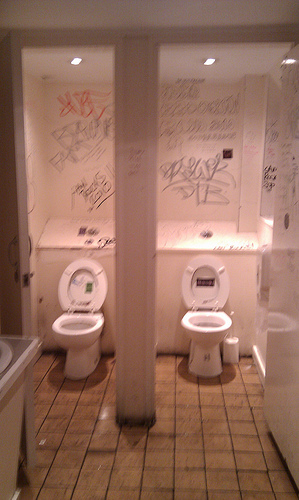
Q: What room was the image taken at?
A: It was taken at the bathroom.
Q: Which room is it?
A: It is a bathroom.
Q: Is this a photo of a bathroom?
A: Yes, it is showing a bathroom.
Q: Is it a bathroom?
A: Yes, it is a bathroom.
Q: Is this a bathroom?
A: Yes, it is a bathroom.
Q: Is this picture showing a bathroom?
A: Yes, it is showing a bathroom.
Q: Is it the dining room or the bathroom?
A: It is the bathroom.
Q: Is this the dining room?
A: No, it is the bathroom.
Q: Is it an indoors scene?
A: Yes, it is indoors.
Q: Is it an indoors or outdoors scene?
A: It is indoors.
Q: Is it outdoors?
A: No, it is indoors.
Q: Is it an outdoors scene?
A: No, it is indoors.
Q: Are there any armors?
A: No, there are no armors.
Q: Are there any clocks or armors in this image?
A: No, there are no armors or clocks.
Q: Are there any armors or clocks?
A: No, there are no armors or clocks.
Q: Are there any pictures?
A: No, there are no pictures.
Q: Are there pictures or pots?
A: No, there are no pictures or pots.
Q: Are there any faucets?
A: No, there are no faucets.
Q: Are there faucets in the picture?
A: No, there are no faucets.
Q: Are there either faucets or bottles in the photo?
A: No, there are no faucets or bottles.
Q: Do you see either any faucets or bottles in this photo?
A: No, there are no faucets or bottles.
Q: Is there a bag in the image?
A: No, there are no bags.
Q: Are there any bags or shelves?
A: No, there are no bags or shelves.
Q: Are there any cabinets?
A: No, there are no cabinets.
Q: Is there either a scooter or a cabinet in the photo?
A: No, there are no cabinets or scooters.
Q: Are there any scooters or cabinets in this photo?
A: No, there are no cabinets or scooters.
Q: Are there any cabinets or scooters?
A: No, there are no cabinets or scooters.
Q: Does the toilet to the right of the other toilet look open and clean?
A: Yes, the toilet is open and clean.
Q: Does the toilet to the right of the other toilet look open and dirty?
A: No, the toilet is open but clean.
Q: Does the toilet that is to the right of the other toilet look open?
A: Yes, the toilet is open.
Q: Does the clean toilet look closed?
A: No, the toilet is open.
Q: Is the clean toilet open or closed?
A: The toilet is open.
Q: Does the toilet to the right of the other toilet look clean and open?
A: Yes, the toilet is clean and open.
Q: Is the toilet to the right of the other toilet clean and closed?
A: No, the toilet is clean but open.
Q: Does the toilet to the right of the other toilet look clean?
A: Yes, the toilet is clean.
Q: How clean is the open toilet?
A: The toilet is clean.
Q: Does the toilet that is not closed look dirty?
A: No, the toilet is clean.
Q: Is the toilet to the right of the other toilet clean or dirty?
A: The toilet is clean.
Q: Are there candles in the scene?
A: No, there are no candles.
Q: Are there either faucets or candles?
A: No, there are no candles or faucets.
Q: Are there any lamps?
A: No, there are no lamps.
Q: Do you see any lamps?
A: No, there are no lamps.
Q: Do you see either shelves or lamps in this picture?
A: No, there are no lamps or shelves.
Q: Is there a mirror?
A: Yes, there is a mirror.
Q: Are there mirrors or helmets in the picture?
A: Yes, there is a mirror.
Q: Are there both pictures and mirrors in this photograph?
A: No, there is a mirror but no pictures.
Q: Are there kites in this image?
A: No, there are no kites.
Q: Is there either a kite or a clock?
A: No, there are no kites or clocks.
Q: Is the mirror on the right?
A: Yes, the mirror is on the right of the image.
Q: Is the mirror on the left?
A: No, the mirror is on the right of the image.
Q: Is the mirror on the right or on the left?
A: The mirror is on the right of the image.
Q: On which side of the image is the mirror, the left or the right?
A: The mirror is on the right of the image.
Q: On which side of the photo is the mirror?
A: The mirror is on the right of the image.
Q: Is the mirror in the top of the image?
A: Yes, the mirror is in the top of the image.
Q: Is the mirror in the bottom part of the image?
A: No, the mirror is in the top of the image.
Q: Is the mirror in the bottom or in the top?
A: The mirror is in the top of the image.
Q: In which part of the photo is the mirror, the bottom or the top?
A: The mirror is in the top of the image.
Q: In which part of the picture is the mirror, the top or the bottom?
A: The mirror is in the top of the image.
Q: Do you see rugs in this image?
A: No, there are no rugs.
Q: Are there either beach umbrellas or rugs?
A: No, there are no rugs or beach umbrellas.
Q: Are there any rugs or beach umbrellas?
A: No, there are no rugs or beach umbrellas.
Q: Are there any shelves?
A: No, there are no shelves.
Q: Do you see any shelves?
A: No, there are no shelves.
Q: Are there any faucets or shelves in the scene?
A: No, there are no shelves or faucets.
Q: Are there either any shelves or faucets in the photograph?
A: No, there are no shelves or faucets.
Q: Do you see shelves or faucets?
A: No, there are no shelves or faucets.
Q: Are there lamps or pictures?
A: No, there are no pictures or lamps.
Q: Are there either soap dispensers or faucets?
A: No, there are no faucets or soap dispensers.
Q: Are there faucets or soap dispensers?
A: No, there are no faucets or soap dispensers.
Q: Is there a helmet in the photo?
A: No, there are no helmets.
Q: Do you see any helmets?
A: No, there are no helmets.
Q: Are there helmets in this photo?
A: No, there are no helmets.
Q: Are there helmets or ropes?
A: No, there are no helmets or ropes.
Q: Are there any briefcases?
A: No, there are no briefcases.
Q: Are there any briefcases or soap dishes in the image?
A: No, there are no briefcases or soap dishes.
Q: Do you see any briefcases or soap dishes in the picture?
A: No, there are no briefcases or soap dishes.